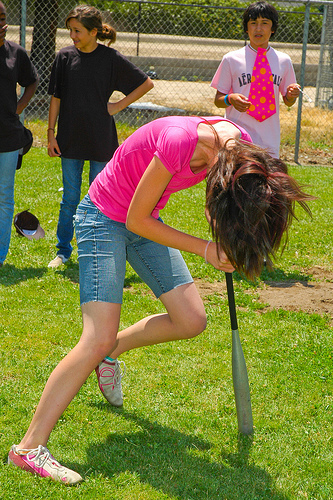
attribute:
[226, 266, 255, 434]
bat — silver, black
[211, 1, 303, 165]
boy — watching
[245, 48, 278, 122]
tie — pink, yellow, gold, wide, purple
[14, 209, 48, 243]
cap — black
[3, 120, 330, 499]
grass — green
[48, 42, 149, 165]
shirt — black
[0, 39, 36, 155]
shirt — black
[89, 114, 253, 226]
shirt — pink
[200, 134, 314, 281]
hair — brown, streaked, red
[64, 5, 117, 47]
hair — brown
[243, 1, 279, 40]
hair — black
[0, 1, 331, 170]
fence — chain linked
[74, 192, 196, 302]
shorts — blue, jean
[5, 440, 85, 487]
shoe — pink, white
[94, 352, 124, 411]
shoe — pink, white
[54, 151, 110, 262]
jeans — blue